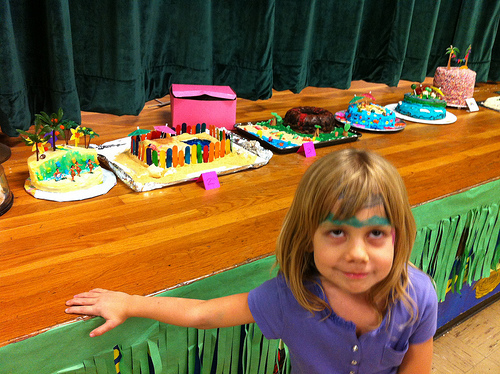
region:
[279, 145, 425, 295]
Child's face smirking to the camera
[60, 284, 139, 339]
Child hands on the stage near the edge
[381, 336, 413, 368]
Pocket on the purple T-shirt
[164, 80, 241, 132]
Pink box on the stage near the cake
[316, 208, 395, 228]
Green face paint on the forehead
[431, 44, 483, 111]
Red cake on the far end next to the blue cake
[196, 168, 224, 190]
Small pink note near the cake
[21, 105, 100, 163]
Cake tree design on top of the cake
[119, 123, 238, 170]
Small fence cake design on top the cake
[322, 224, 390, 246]
Child's eyes looking upward of the camera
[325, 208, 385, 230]
blue paint on a face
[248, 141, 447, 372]
a girl wearing a purple shirt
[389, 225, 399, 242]
pink paint on a face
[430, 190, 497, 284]
green fringe on a table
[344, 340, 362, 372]
small white buttons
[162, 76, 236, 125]
a pink boy on the table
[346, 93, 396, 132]
a blue cake with colorful sprinkles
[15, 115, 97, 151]
plastic trees on top of a cake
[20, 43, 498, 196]
a table full of colorful cakes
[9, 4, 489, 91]
a blue velvet curtain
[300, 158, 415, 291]
a little girl with paint on her face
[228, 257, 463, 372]
a child wearing a purple shirt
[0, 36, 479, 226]
a display of cakes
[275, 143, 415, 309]
a girl with blonde hair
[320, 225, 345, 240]
a person's right eye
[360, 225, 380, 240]
a person's left eye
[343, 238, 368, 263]
a person's nose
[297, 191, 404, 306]
a smiling little girl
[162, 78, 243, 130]
a pink cardboard box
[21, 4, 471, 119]
a dark green stage curtain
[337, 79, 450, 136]
two cakes on the table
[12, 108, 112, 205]
beach scene on the cake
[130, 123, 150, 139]
umbrella on the cake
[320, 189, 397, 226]
paint on the forehead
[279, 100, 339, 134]
cake shaped like a volcano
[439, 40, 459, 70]
palm tree on the cake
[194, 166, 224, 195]
place cards on the table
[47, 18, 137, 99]
green curtain behind the cakes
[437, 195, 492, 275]
paper grass on the table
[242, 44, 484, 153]
beach themed cakes on the table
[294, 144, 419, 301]
A little girl with paint on her face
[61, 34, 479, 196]
Cakes decorated on a table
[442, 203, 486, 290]
Green paper that looks like grass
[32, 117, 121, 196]
This is a yellow cake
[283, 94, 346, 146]
A chocolate bundt cake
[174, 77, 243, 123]
A pink cardboard cake box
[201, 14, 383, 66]
A heavy green curtain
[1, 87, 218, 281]
This is a stage at a school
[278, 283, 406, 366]
The girls shirt is purple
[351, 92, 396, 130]
A cake frosted with blue frosting